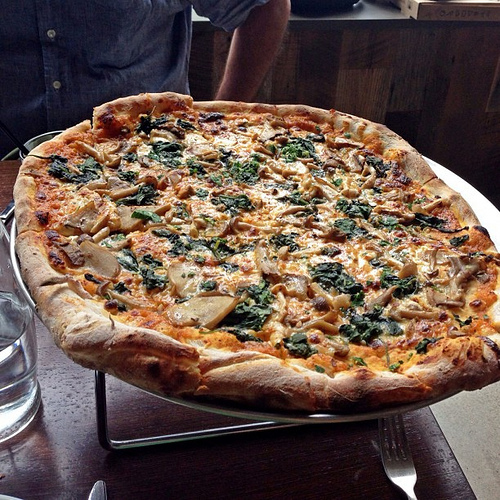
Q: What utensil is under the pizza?
A: A fork.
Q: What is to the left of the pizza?
A: A half full glass of water.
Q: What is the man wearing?
A: A blue shirt.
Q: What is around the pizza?
A: A dry pizza crust.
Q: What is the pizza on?
A: A dark wood table.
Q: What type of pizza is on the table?
A: An uncut vegetable pizza.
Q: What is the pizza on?
A: A metal pizza stand.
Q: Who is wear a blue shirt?
A: The man sitting at the table.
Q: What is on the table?
A: A large round pizza.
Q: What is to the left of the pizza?
A: A glass with water?.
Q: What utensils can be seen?
A: Knife and fork.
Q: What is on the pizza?
A: Cheese, sauce, spinach and mushrooms.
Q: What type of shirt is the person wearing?
A: Blue denim.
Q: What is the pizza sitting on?
A: A metal tray.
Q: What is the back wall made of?
A: Brown wood.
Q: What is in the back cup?
A: A black straw.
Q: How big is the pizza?
A: Very big.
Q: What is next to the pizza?
A: Glass.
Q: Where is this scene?
A: Restaurant.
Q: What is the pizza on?
A: Stand.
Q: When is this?
A: Daytime.